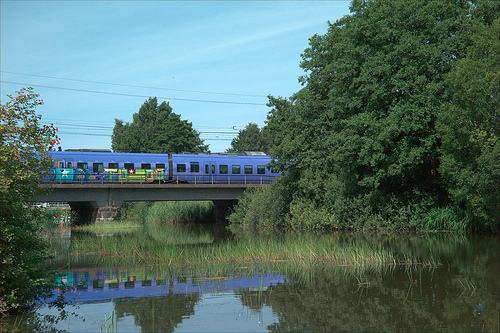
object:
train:
[9, 148, 296, 188]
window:
[191, 162, 199, 175]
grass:
[43, 210, 458, 273]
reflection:
[28, 256, 500, 331]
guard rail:
[31, 170, 282, 183]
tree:
[227, 0, 500, 235]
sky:
[2, 2, 352, 159]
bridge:
[7, 181, 274, 222]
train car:
[172, 151, 282, 183]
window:
[94, 161, 105, 174]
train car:
[31, 150, 170, 184]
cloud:
[1, 0, 355, 152]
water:
[12, 216, 500, 332]